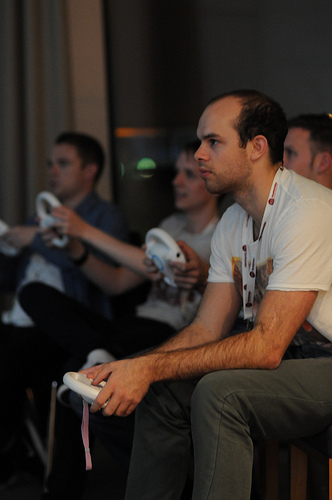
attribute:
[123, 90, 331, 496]
man — balding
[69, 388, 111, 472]
wristband — pink